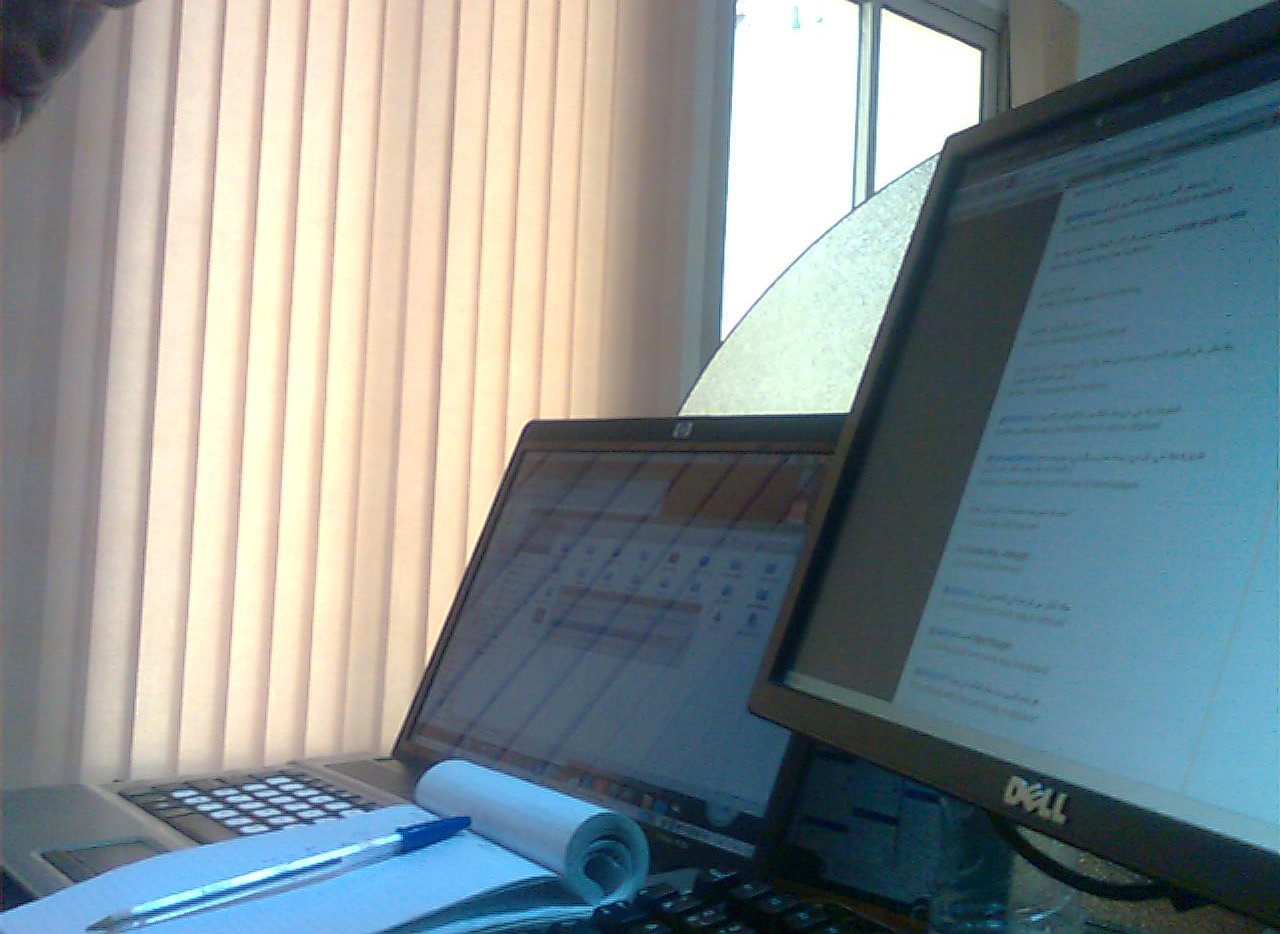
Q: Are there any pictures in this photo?
A: No, there are no pictures.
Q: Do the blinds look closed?
A: Yes, the blinds are closed.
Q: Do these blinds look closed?
A: Yes, the blinds are closed.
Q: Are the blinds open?
A: No, the blinds are closed.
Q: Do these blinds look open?
A: No, the blinds are closed.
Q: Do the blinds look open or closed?
A: The blinds are closed.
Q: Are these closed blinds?
A: Yes, these are closed blinds.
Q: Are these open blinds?
A: No, these are closed blinds.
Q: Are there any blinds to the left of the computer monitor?
A: Yes, there are blinds to the left of the computer monitor.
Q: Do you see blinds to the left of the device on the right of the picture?
A: Yes, there are blinds to the left of the computer monitor.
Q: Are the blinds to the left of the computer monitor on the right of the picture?
A: Yes, the blinds are to the left of the computer monitor.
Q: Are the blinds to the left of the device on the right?
A: Yes, the blinds are to the left of the computer monitor.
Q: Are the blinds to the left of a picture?
A: No, the blinds are to the left of the computer monitor.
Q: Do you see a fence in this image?
A: No, there are no fences.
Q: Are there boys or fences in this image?
A: No, there are no fences or boys.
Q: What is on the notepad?
A: The pen is on the notepad.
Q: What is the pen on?
A: The pen is on the notepad.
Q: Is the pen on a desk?
A: No, the pen is on a notepad.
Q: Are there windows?
A: Yes, there are windows.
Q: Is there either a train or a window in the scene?
A: Yes, there are windows.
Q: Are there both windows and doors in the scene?
A: Yes, there are both windows and a door.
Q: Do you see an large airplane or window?
A: Yes, there are large windows.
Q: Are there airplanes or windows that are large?
A: Yes, the windows are large.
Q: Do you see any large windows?
A: Yes, there are large windows.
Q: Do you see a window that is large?
A: Yes, there are windows that are large.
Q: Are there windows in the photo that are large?
A: Yes, there are windows that are large.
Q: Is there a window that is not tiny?
A: Yes, there are large windows.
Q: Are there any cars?
A: No, there are no cars.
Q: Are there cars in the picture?
A: No, there are no cars.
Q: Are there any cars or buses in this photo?
A: No, there are no cars or buses.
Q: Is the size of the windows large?
A: Yes, the windows are large.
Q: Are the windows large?
A: Yes, the windows are large.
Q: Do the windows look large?
A: Yes, the windows are large.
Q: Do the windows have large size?
A: Yes, the windows are large.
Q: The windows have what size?
A: The windows are large.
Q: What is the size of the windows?
A: The windows are large.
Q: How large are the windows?
A: The windows are large.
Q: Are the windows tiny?
A: No, the windows are large.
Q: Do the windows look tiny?
A: No, the windows are large.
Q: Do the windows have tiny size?
A: No, the windows are large.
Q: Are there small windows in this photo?
A: No, there are windows but they are large.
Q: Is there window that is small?
A: No, there are windows but they are large.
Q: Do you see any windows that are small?
A: No, there are windows but they are large.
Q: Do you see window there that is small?
A: No, there are windows but they are large.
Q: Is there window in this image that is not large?
A: No, there are windows but they are large.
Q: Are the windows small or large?
A: The windows are large.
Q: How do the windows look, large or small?
A: The windows are large.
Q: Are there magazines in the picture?
A: No, there are no magazines.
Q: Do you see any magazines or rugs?
A: No, there are no magazines or rugs.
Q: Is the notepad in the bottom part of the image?
A: Yes, the notepad is in the bottom of the image.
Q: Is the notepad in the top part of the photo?
A: No, the notepad is in the bottom of the image.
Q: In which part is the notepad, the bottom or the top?
A: The notepad is in the bottom of the image.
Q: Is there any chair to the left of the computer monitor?
A: No, there is a notepad to the left of the computer monitor.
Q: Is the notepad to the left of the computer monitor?
A: Yes, the notepad is to the left of the computer monitor.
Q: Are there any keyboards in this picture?
A: Yes, there is a keyboard.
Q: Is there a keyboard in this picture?
A: Yes, there is a keyboard.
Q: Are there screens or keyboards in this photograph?
A: Yes, there is a keyboard.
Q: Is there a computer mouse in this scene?
A: No, there are no computer mice.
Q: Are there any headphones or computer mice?
A: No, there are no computer mice or headphones.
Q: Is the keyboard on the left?
A: Yes, the keyboard is on the left of the image.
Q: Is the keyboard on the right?
A: No, the keyboard is on the left of the image.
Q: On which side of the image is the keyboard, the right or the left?
A: The keyboard is on the left of the image.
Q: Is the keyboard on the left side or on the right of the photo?
A: The keyboard is on the left of the image.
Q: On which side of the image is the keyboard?
A: The keyboard is on the left of the image.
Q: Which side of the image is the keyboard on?
A: The keyboard is on the left of the image.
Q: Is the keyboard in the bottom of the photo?
A: Yes, the keyboard is in the bottom of the image.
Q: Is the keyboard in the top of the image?
A: No, the keyboard is in the bottom of the image.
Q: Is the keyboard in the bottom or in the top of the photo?
A: The keyboard is in the bottom of the image.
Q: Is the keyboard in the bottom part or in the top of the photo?
A: The keyboard is in the bottom of the image.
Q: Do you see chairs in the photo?
A: No, there are no chairs.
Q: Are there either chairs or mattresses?
A: No, there are no chairs or mattresses.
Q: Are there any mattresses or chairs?
A: No, there are no chairs or mattresses.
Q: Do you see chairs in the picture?
A: No, there are no chairs.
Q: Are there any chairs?
A: No, there are no chairs.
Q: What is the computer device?
A: The device is a computer monitor.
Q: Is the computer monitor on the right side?
A: Yes, the computer monitor is on the right of the image.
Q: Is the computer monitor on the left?
A: No, the computer monitor is on the right of the image.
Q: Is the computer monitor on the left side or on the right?
A: The computer monitor is on the right of the image.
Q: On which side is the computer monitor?
A: The computer monitor is on the right of the image.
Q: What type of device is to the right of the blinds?
A: The device is a computer monitor.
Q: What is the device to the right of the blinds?
A: The device is a computer monitor.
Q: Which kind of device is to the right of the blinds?
A: The device is a computer monitor.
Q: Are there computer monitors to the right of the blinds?
A: Yes, there is a computer monitor to the right of the blinds.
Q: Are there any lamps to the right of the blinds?
A: No, there is a computer monitor to the right of the blinds.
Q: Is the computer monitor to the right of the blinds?
A: Yes, the computer monitor is to the right of the blinds.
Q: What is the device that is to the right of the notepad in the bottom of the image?
A: The device is a computer monitor.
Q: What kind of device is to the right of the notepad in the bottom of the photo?
A: The device is a computer monitor.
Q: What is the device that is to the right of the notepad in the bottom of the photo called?
A: The device is a computer monitor.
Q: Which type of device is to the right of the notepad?
A: The device is a computer monitor.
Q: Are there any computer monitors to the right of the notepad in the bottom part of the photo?
A: Yes, there is a computer monitor to the right of the notepad.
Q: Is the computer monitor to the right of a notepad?
A: Yes, the computer monitor is to the right of a notepad.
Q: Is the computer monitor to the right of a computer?
A: No, the computer monitor is to the right of a notepad.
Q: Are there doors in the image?
A: Yes, there is a door.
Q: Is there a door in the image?
A: Yes, there is a door.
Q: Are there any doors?
A: Yes, there is a door.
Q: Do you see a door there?
A: Yes, there is a door.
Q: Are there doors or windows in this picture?
A: Yes, there is a door.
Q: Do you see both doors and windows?
A: Yes, there are both a door and windows.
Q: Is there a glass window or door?
A: Yes, there is a glass door.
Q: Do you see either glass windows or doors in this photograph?
A: Yes, there is a glass door.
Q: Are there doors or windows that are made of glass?
A: Yes, the door is made of glass.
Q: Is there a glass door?
A: Yes, there is a door that is made of glass.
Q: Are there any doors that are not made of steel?
A: Yes, there is a door that is made of glass.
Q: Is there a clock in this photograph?
A: No, there are no clocks.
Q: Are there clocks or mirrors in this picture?
A: No, there are no clocks or mirrors.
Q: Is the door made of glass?
A: Yes, the door is made of glass.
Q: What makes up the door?
A: The door is made of glass.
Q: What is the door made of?
A: The door is made of glass.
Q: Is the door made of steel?
A: No, the door is made of glass.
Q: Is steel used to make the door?
A: No, the door is made of glass.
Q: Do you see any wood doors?
A: No, there is a door but it is made of glass.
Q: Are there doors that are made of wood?
A: No, there is a door but it is made of glass.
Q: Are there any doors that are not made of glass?
A: No, there is a door but it is made of glass.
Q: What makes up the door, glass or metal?
A: The door is made of glass.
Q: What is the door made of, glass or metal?
A: The door is made of glass.